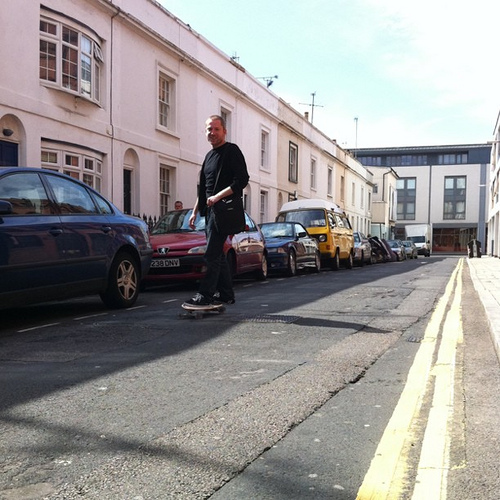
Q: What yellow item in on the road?
A: A line.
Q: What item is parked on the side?
A: Cars.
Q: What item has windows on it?
A: A building.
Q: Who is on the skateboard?
A: A man.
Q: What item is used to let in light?
A: A window.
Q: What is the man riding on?
A: A skateboard.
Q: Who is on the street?
A: Man on a skateboard.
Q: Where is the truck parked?
A: At the end of the street.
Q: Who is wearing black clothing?
A: The man on the skateboard.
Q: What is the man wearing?
A: A jacket.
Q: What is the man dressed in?
A: Black.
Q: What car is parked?
A: A red car.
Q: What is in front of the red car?
A: A blue car.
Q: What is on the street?
A: A painted line.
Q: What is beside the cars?
A: Building.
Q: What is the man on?
A: A skateboard.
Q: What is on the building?
A: Windows.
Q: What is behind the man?
A: A building.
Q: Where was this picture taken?
A: On a road.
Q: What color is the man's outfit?
A: Black.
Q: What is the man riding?
A: A skateboard.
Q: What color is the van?
A: Yellow.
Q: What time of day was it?
A: Daytime.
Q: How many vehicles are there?
A: Eight.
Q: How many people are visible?
A: Two.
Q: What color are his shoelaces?
A: White.